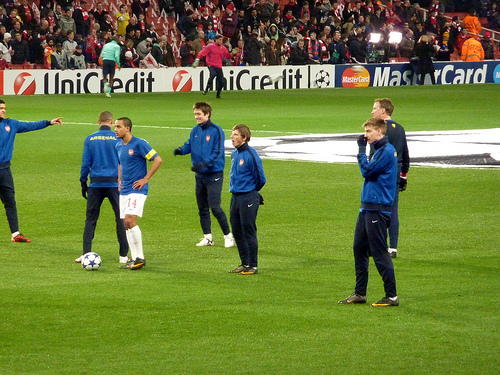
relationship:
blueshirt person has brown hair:
[335, 118, 398, 307] [360, 118, 385, 137]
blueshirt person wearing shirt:
[113, 117, 164, 271] [113, 132, 160, 199]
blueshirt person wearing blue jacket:
[335, 118, 398, 307] [356, 141, 401, 211]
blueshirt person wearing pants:
[335, 118, 398, 307] [340, 197, 411, 317]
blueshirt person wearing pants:
[227, 124, 266, 276] [230, 190, 260, 270]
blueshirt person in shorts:
[113, 117, 164, 271] [113, 191, 148, 219]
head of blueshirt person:
[365, 123, 385, 142] [335, 118, 398, 307]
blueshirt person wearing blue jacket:
[113, 117, 164, 271] [357, 135, 399, 215]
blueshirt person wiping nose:
[335, 118, 398, 307] [367, 107, 377, 117]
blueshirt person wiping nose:
[227, 124, 266, 276] [227, 132, 238, 142]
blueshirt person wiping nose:
[173, 102, 237, 250] [110, 125, 121, 137]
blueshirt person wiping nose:
[113, 117, 164, 271] [187, 111, 201, 123]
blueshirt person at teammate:
[173, 102, 237, 250] [0, 84, 410, 313]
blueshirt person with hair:
[173, 102, 237, 250] [188, 96, 211, 118]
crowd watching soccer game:
[250, 14, 476, 59] [0, 93, 480, 373]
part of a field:
[144, 301, 269, 372] [86, 269, 300, 364]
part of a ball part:
[87, 254, 97, 268] [89, 253, 107, 271]